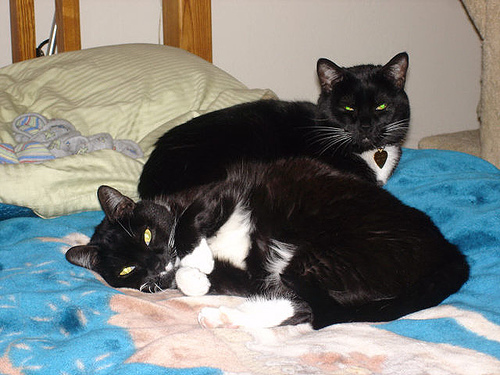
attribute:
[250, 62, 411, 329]
cats — black, yellow, sleeping, laying, resting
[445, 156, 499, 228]
bed — blue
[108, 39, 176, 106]
pillow — white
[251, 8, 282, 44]
wall — white